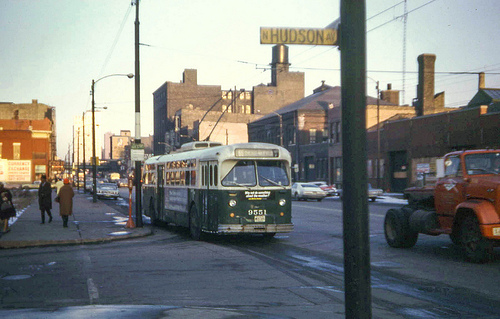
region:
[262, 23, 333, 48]
Rectangular street sign that reads Hudson.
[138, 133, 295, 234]
A green and silver city bus.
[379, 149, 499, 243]
A red old style vehicle on the road.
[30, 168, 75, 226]
Two people walking on the sidewalk.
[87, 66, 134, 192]
Tall wooden street post with metal street light.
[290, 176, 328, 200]
Old white sedan vehicle driving on the road.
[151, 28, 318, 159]
Factory style brown city building.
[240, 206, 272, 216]
White bus number reading 9551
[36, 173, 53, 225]
Man wearing a winter coat and hat.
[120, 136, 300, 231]
old green and white bus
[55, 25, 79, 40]
white clouds in blue sky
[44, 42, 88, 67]
white clouds in blue sky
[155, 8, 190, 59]
white clouds in blue sky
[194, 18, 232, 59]
white clouds in blue sky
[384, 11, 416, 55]
white clouds in blue sky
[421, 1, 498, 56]
white clouds in blue sky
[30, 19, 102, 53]
white clouds in blue sky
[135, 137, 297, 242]
green and white bus on the street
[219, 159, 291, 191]
windshield on a green and white bus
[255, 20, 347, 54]
yellow sign with black writing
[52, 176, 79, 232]
person walking on the sidewalk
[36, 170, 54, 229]
person walking on the sidewalk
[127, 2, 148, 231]
black street light pole made of metal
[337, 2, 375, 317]
black street light pole made of metal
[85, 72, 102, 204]
black street light pole made of metal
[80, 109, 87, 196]
black street light pole made of metal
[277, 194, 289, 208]
headlight on the front of the bus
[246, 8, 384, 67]
A vintage street sign reading North Hudson Avenue.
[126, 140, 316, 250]
A green city bus number 9551.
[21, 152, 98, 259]
People walking down the street on a cold winter day.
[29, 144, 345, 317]
The roads are dry but there is still a bit of ice in spots.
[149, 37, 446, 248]
An industrial down town area with lots of brick buildings.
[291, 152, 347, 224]
Vintage cars drive down the road.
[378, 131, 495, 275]
An interesting red work truck is on the road.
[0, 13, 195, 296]
The sun is rising on a cold winter day.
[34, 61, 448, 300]
People making their way to their day in a down town area.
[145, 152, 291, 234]
A green and silver city bus.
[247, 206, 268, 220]
City bus number 9551 in white numbers.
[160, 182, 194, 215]
An advertisement on the side of the city bus.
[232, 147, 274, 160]
A computed sign on the top of the bus reading destination.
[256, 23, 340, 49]
A rectangular street sign for North Hudson Avenue.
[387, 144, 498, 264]
An old style red vehicle on the road.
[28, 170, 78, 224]
A man and a woman walking along the sidewalk.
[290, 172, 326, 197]
An old white vehicle on the road.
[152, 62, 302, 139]
A factory style brown city building.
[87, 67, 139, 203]
A large wooden street post with a street light.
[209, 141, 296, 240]
The front end of the trolley car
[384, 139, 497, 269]
A copper colored truck in the road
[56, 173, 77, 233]
A person walking on the sidewalk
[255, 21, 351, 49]
a street sign name Hudson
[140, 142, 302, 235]
a trolley car by the curb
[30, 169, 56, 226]
A person wearing a black coat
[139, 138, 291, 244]
a green and white public service bus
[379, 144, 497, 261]
an orange pick up truck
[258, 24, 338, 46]
a street name sign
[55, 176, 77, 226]
a pedestrian on sidewalk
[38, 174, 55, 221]
a pedestrian on sidewalk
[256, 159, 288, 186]
a bus front windshield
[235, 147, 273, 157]
a bus destination sign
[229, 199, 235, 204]
a bus front headlight